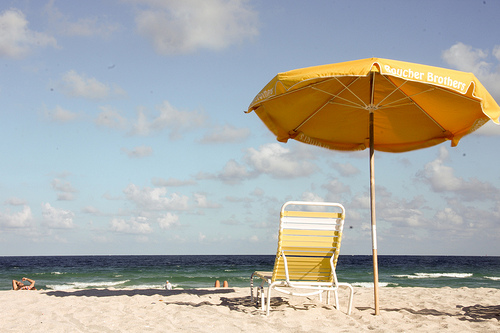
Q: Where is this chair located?
A: Beach.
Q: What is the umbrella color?
A: Yellow.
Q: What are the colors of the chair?
A: Yellow and white.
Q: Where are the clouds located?
A: Sky.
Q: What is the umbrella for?
A: Shade.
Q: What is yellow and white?
A: Chair.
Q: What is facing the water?
A: Chair.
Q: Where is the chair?
A: On the sand.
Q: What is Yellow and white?
A: Chair.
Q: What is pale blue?
A: Sky.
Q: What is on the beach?
A: Chair.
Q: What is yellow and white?
A: Chair.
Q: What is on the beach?
A: Parasol.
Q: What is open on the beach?
A: Umbrella.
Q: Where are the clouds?
A: Sky.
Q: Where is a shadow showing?
A: Sand.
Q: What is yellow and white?
A: Beach chair.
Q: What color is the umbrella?
A: Yellow.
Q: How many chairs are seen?
A: 1.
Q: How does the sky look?
A: A little cloudy.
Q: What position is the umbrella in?
A: Open.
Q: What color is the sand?
A: Light brown.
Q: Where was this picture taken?
A: A beach.